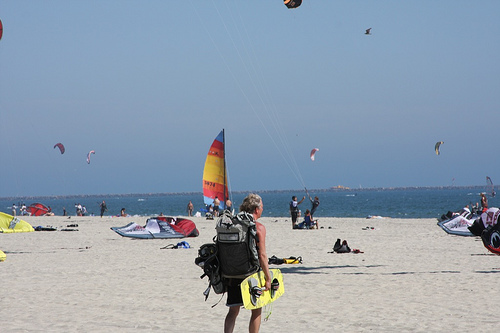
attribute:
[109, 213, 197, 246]
vehicle — small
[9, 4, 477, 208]
sky — blue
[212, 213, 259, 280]
backpack — gray, black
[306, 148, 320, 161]
kite — big, white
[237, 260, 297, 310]
board — yellow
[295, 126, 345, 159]
kite — pink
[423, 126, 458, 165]
kite — pink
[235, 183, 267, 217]
hair — gray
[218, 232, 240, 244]
patch — small, gray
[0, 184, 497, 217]
sea — wavy, blue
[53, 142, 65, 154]
parasail — red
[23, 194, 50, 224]
patch — big, red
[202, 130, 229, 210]
sail — multicolored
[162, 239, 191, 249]
object — small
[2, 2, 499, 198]
sky — clear, blue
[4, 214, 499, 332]
beach — massive, gray